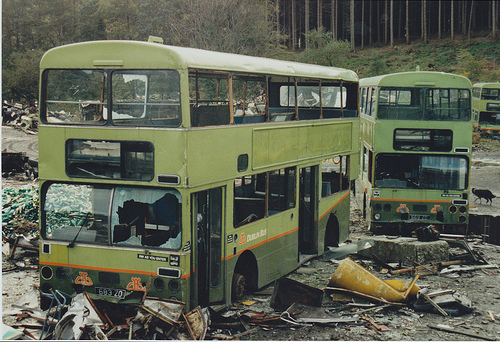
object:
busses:
[357, 64, 478, 240]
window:
[110, 180, 184, 252]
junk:
[322, 249, 429, 308]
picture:
[0, 0, 499, 341]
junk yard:
[0, 0, 499, 341]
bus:
[30, 34, 362, 315]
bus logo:
[121, 273, 148, 295]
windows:
[179, 66, 231, 129]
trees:
[0, 0, 295, 112]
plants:
[0, 0, 499, 106]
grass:
[350, 29, 500, 97]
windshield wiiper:
[64, 208, 97, 252]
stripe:
[38, 259, 196, 283]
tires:
[219, 249, 266, 308]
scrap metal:
[265, 270, 329, 314]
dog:
[468, 184, 498, 207]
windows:
[230, 71, 273, 129]